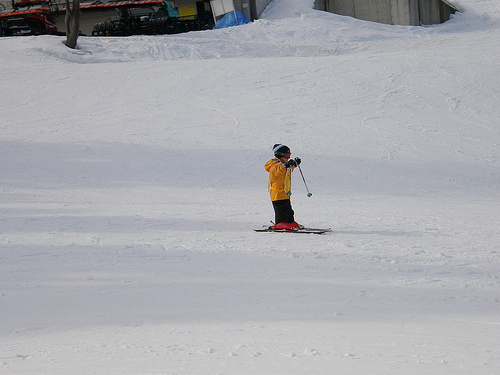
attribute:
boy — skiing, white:
[246, 132, 322, 247]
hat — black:
[272, 140, 289, 156]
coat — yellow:
[267, 160, 293, 199]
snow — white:
[6, 32, 492, 374]